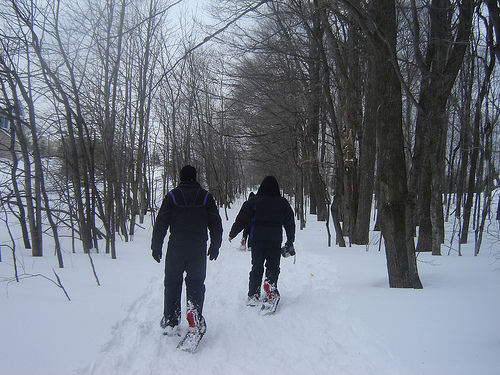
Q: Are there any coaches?
A: No, there are no coaches.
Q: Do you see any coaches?
A: No, there are no coaches.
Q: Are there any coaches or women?
A: No, there are no coaches or women.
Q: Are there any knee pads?
A: No, there are no knee pads.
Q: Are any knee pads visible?
A: No, there are no knee pads.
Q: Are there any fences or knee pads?
A: No, there are no knee pads or fences.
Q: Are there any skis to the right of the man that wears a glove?
A: Yes, there is a ski to the right of the man.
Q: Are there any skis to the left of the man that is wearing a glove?
A: No, the ski is to the right of the man.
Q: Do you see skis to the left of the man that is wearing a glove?
A: No, the ski is to the right of the man.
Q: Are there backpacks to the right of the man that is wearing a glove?
A: No, there is a ski to the right of the man.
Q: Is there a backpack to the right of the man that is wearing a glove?
A: No, there is a ski to the right of the man.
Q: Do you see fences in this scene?
A: No, there are no fences.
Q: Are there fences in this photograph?
A: No, there are no fences.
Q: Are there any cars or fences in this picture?
A: No, there are no fences or cars.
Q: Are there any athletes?
A: No, there are no athletes.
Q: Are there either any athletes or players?
A: No, there are no athletes or players.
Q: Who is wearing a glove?
A: The man is wearing a glove.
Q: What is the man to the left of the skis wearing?
A: The man is wearing a glove.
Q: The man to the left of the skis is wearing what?
A: The man is wearing a glove.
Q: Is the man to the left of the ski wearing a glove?
A: Yes, the man is wearing a glove.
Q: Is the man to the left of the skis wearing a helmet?
A: No, the man is wearing a glove.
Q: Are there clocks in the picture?
A: No, there are no clocks.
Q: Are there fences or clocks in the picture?
A: No, there are no clocks or fences.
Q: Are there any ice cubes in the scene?
A: No, there are no ice cubes.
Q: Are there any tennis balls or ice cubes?
A: No, there are no ice cubes or tennis balls.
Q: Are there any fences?
A: No, there are no fences.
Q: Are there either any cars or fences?
A: No, there are no fences or cars.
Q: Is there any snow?
A: Yes, there is snow.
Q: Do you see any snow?
A: Yes, there is snow.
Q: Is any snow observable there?
A: Yes, there is snow.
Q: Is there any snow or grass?
A: Yes, there is snow.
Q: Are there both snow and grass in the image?
A: No, there is snow but no grass.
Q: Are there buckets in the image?
A: No, there are no buckets.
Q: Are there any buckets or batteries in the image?
A: No, there are no buckets or batteries.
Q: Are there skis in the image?
A: Yes, there are skis.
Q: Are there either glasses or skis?
A: Yes, there are skis.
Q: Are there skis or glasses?
A: Yes, there are skis.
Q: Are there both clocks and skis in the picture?
A: No, there are skis but no clocks.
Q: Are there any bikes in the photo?
A: No, there are no bikes.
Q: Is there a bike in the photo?
A: No, there are no bikes.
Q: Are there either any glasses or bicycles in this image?
A: No, there are no bicycles or glasses.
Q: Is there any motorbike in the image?
A: No, there are no motorcycles.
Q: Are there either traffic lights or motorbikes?
A: No, there are no motorbikes or traffic lights.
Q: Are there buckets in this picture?
A: No, there are no buckets.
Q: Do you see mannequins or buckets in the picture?
A: No, there are no buckets or mannequins.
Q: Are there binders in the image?
A: No, there are no binders.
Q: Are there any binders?
A: No, there are no binders.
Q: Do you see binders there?
A: No, there are no binders.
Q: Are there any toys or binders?
A: No, there are no binders or toys.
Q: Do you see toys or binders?
A: No, there are no binders or toys.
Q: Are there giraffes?
A: No, there are no giraffes.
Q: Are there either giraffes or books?
A: No, there are no giraffes or books.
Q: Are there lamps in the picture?
A: No, there are no lamps.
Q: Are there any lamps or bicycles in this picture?
A: No, there are no lamps or bicycles.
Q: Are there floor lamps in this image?
A: No, there are no floor lamps.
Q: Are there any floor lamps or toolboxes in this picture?
A: No, there are no floor lamps or toolboxes.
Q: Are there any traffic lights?
A: No, there are no traffic lights.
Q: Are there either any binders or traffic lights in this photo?
A: No, there are no traffic lights or binders.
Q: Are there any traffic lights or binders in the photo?
A: No, there are no traffic lights or binders.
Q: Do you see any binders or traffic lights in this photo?
A: No, there are no traffic lights or binders.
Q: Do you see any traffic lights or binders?
A: No, there are no traffic lights or binders.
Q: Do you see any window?
A: Yes, there are windows.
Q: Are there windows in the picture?
A: Yes, there are windows.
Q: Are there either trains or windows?
A: Yes, there are windows.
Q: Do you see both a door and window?
A: No, there are windows but no doors.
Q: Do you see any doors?
A: No, there are no doors.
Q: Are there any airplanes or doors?
A: No, there are no doors or airplanes.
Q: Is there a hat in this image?
A: Yes, there is a hat.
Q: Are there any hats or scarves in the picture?
A: Yes, there is a hat.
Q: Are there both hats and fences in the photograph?
A: No, there is a hat but no fences.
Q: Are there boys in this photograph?
A: No, there are no boys.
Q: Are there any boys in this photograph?
A: No, there are no boys.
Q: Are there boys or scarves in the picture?
A: No, there are no boys or scarves.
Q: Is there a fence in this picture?
A: No, there are no fences.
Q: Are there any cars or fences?
A: No, there are no fences or cars.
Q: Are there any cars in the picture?
A: No, there are no cars.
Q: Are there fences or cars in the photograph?
A: No, there are no cars or fences.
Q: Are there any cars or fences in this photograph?
A: No, there are no cars or fences.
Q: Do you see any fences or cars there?
A: No, there are no cars or fences.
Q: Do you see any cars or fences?
A: No, there are no cars or fences.